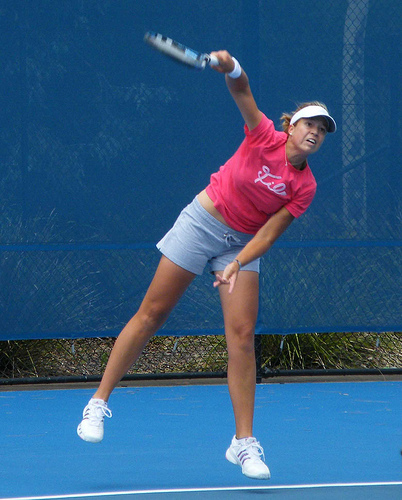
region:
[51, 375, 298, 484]
woman wearing white shoes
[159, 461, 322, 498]
blue court with white lines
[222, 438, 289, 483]
stripes on shoes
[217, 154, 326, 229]
shirt is red with letters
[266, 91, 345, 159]
woman with white visor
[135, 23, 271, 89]
woman with black racket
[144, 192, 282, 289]
woman wearing grey shorts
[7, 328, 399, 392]
black chain link fence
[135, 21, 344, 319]
woman swinging racket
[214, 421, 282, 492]
shoe laces are tied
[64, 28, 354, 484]
Young woman playing tennis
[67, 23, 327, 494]
Tennis player serving from end line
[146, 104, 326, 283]
Woman in blue shorts and red top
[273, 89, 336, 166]
Woman wearing white visor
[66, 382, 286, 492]
Two tennis shoes in air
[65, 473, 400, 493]
White chalk tennis court end line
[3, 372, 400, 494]
Blue tennis court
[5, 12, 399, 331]
Blue tarp covering fence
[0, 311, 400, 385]
Black chain link fence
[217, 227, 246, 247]
Tightening strings on shorts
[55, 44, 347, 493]
woman wears red shirt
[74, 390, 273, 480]
white shoes with blue stripes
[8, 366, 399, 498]
floor of tennis court is blue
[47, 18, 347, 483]
tennis player wears blue shorts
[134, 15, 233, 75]
a white, blue and black racket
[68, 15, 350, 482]
tennis player is jumping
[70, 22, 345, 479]
tennis player holds a racket in right hand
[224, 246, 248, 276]
a bracelet on a wrist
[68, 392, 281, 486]
white shoes has white pins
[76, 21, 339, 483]
A woman playing tennis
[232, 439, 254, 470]
Stripes on a white sneaker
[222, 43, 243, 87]
A white arm band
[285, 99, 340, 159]
White visor on woman's head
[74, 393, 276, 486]
A pair of white sneakers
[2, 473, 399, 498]
White line on the court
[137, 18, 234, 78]
Tennis racket in a hand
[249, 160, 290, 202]
White writing on red shirt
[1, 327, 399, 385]
A fence behind the player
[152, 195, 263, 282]
A pair of gray shorts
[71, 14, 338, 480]
a woman playing tennis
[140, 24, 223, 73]
a tennis racket in the girl's right hand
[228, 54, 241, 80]
a white sweatband on the girl's wrist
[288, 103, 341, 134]
a white visor on the girl's head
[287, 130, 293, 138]
an earring in the girl's ear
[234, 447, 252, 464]
Adidas stripes on the tennis shoes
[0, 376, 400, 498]
a blue tennis court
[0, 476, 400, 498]
a white line painted on the tennis court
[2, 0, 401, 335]
a blue mesh divider behind the tennis court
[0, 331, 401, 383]
a black chain link fence behind the tennis court